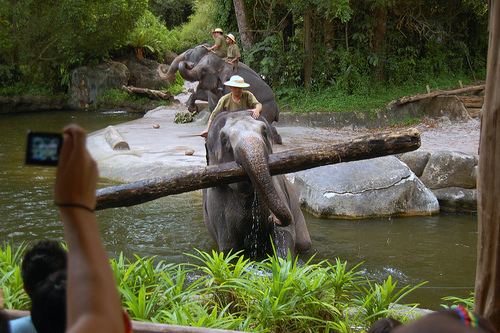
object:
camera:
[23, 129, 67, 167]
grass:
[274, 84, 477, 115]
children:
[11, 235, 132, 332]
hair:
[20, 239, 69, 331]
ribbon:
[455, 306, 478, 329]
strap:
[54, 201, 96, 214]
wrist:
[55, 193, 95, 229]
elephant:
[200, 110, 314, 263]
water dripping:
[249, 187, 265, 259]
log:
[93, 127, 422, 212]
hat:
[222, 75, 251, 88]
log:
[105, 125, 130, 150]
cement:
[84, 81, 482, 196]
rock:
[291, 155, 441, 222]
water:
[1, 107, 488, 320]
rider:
[201, 74, 263, 142]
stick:
[177, 134, 207, 138]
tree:
[382, 81, 487, 113]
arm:
[50, 126, 127, 332]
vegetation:
[1, 2, 482, 112]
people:
[207, 28, 227, 58]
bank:
[4, 76, 488, 221]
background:
[2, 5, 489, 142]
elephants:
[177, 54, 292, 127]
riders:
[215, 33, 241, 93]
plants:
[341, 275, 428, 333]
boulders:
[66, 60, 130, 109]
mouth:
[230, 141, 270, 179]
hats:
[213, 28, 225, 33]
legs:
[183, 90, 208, 108]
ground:
[70, 98, 483, 221]